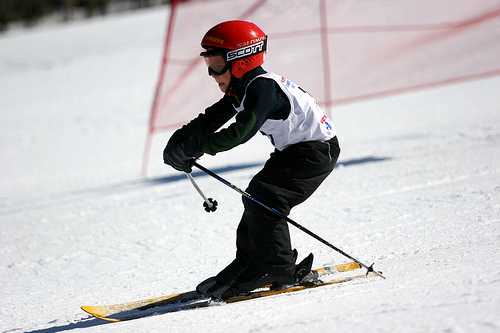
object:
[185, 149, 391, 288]
ski pole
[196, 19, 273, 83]
helmet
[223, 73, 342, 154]
jersey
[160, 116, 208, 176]
gloves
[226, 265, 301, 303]
boot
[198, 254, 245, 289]
boot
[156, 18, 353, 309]
boy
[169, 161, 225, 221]
ski pole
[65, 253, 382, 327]
skis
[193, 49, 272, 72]
goggles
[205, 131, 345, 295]
pants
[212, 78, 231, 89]
mouth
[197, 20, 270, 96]
head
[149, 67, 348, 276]
suit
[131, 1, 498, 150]
snow fence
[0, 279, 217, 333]
shadow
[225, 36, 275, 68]
strap